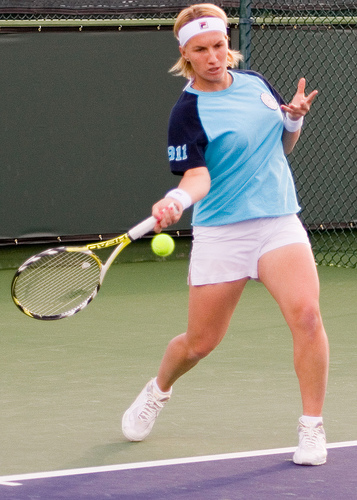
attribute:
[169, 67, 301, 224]
shirt — two-toned, blue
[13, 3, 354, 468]
woman — playing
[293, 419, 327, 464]
sneaker — white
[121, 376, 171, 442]
sneaker — white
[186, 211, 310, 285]
tennis skirt — white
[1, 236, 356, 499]
floor — purple , green, white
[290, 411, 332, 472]
shoe — white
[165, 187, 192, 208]
wristband — White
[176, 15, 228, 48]
headband — white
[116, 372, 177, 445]
shoe — white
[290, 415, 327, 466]
tennis shoe — white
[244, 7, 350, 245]
fence — around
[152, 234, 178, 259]
ball — mid air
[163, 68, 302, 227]
top — light blue , navy blue 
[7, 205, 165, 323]
racket — yellow, black, white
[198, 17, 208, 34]
logo — Fila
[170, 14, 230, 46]
headband — tennis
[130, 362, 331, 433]
socks — white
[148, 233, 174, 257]
tennis ball — green, Yellow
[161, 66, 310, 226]
shirt — blue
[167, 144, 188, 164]
911 — blue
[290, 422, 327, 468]
shoe — white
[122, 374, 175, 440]
shoe — white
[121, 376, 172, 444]
shoe — white